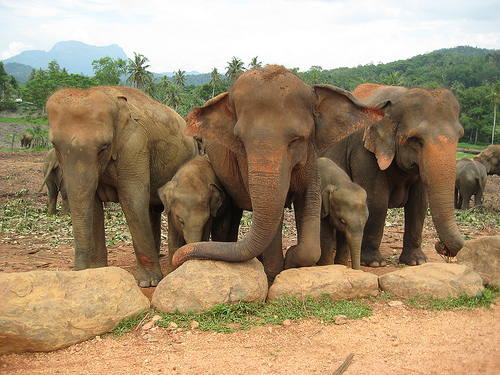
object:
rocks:
[0, 264, 154, 355]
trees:
[18, 55, 101, 126]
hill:
[344, 44, 484, 87]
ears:
[360, 100, 403, 172]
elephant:
[37, 148, 69, 217]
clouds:
[314, 13, 377, 68]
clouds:
[159, 8, 239, 55]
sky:
[72, 0, 488, 116]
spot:
[421, 128, 463, 208]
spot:
[243, 144, 293, 195]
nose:
[170, 146, 295, 265]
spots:
[194, 111, 215, 142]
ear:
[183, 92, 246, 160]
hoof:
[284, 242, 322, 273]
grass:
[223, 295, 377, 328]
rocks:
[458, 232, 499, 290]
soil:
[227, 315, 363, 371]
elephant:
[156, 157, 225, 274]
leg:
[108, 144, 161, 266]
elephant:
[455, 154, 488, 212]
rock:
[267, 260, 380, 307]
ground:
[276, 297, 425, 364]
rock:
[379, 259, 496, 306]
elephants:
[49, 60, 478, 250]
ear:
[311, 83, 385, 161]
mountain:
[11, 36, 141, 66]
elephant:
[185, 63, 386, 282]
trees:
[92, 55, 131, 93]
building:
[8, 98, 40, 109]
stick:
[324, 343, 361, 375]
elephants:
[45, 84, 198, 288]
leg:
[298, 176, 323, 250]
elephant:
[321, 83, 464, 269]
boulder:
[148, 253, 268, 315]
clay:
[135, 254, 156, 273]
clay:
[232, 248, 259, 261]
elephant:
[296, 157, 370, 270]